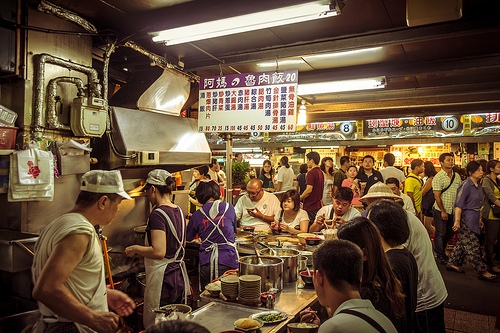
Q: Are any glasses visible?
A: No, there are no glasses.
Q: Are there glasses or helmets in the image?
A: No, there are no glasses or helmets.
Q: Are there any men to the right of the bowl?
A: Yes, there is a man to the right of the bowl.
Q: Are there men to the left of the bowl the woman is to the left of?
A: No, the man is to the right of the bowl.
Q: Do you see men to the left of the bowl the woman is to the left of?
A: No, the man is to the right of the bowl.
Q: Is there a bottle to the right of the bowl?
A: No, there is a man to the right of the bowl.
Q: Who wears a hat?
A: The man wears a hat.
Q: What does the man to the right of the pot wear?
A: The man wears a hat.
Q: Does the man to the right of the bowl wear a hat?
A: Yes, the man wears a hat.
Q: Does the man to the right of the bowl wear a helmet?
A: No, the man wears a hat.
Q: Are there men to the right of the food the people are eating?
A: Yes, there is a man to the right of the food.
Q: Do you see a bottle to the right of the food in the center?
A: No, there is a man to the right of the food.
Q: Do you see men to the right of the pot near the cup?
A: Yes, there is a man to the right of the pot.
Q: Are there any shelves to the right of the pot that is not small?
A: No, there is a man to the right of the pot.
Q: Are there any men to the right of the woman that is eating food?
A: Yes, there is a man to the right of the woman.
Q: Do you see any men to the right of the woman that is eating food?
A: Yes, there is a man to the right of the woman.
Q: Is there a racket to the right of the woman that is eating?
A: No, there is a man to the right of the woman.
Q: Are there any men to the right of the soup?
A: Yes, there is a man to the right of the soup.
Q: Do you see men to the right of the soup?
A: Yes, there is a man to the right of the soup.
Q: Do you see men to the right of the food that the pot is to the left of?
A: Yes, there is a man to the right of the soup.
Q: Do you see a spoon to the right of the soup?
A: No, there is a man to the right of the soup.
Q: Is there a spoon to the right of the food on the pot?
A: No, there is a man to the right of the soup.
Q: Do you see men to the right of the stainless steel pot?
A: Yes, there is a man to the right of the pot.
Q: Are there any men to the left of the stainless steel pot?
A: No, the man is to the right of the pot.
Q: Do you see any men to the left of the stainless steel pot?
A: No, the man is to the right of the pot.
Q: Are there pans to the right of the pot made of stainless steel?
A: No, there is a man to the right of the pot.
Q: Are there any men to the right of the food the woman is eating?
A: Yes, there is a man to the right of the food.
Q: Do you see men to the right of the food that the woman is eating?
A: Yes, there is a man to the right of the food.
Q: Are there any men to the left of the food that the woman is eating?
A: No, the man is to the right of the food.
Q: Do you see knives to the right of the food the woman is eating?
A: No, there is a man to the right of the food.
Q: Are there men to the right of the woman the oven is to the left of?
A: Yes, there is a man to the right of the woman.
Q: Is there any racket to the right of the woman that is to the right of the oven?
A: No, there is a man to the right of the woman.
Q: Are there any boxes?
A: No, there are no boxes.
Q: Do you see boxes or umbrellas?
A: No, there are no boxes or umbrellas.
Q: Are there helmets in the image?
A: No, there are no helmets.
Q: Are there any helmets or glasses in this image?
A: No, there are no helmets or glasses.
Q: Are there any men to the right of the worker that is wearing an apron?
A: Yes, there is a man to the right of the worker.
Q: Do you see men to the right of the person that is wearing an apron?
A: Yes, there is a man to the right of the worker.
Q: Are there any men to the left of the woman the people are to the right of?
A: Yes, there is a man to the left of the woman.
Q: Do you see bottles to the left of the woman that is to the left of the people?
A: No, there is a man to the left of the woman.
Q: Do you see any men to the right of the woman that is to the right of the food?
A: Yes, there is a man to the right of the woman.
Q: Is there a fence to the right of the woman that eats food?
A: No, there is a man to the right of the woman.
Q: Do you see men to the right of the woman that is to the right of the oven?
A: Yes, there is a man to the right of the woman.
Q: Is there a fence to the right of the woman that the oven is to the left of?
A: No, there is a man to the right of the woman.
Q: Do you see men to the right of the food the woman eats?
A: Yes, there is a man to the right of the food.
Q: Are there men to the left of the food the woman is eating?
A: No, the man is to the right of the food.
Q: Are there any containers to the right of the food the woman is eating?
A: No, there is a man to the right of the food.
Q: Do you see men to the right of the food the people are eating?
A: Yes, there is a man to the right of the food.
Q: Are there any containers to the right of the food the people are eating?
A: No, there is a man to the right of the food.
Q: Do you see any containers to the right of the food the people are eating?
A: No, there is a man to the right of the food.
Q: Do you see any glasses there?
A: No, there are no glasses.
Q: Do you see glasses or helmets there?
A: No, there are no glasses or helmets.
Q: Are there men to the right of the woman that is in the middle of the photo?
A: Yes, there is a man to the right of the woman.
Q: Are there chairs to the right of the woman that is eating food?
A: No, there is a man to the right of the woman.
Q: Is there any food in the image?
A: Yes, there is food.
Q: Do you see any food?
A: Yes, there is food.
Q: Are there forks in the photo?
A: No, there are no forks.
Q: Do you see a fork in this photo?
A: No, there are no forks.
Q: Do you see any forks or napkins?
A: No, there are no forks or napkins.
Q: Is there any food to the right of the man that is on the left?
A: Yes, there is food to the right of the man.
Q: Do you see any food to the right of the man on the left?
A: Yes, there is food to the right of the man.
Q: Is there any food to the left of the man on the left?
A: No, the food is to the right of the man.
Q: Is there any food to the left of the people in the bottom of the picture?
A: Yes, there is food to the left of the people.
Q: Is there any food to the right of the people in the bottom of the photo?
A: No, the food is to the left of the people.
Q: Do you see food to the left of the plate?
A: Yes, there is food to the left of the plate.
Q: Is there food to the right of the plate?
A: No, the food is to the left of the plate.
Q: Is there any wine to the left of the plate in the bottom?
A: No, there is food to the left of the plate.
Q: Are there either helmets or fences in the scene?
A: No, there are no fences or helmets.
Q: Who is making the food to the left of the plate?
A: The man is making the food.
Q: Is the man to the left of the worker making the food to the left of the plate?
A: Yes, the man is making the food.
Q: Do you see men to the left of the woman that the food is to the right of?
A: Yes, there is a man to the left of the woman.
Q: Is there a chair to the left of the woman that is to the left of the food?
A: No, there is a man to the left of the woman.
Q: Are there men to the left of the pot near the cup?
A: Yes, there is a man to the left of the pot.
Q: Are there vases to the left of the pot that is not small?
A: No, there is a man to the left of the pot.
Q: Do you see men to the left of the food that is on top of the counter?
A: Yes, there is a man to the left of the food.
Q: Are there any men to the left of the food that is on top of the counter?
A: Yes, there is a man to the left of the food.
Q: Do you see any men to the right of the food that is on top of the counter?
A: No, the man is to the left of the food.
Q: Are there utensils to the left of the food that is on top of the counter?
A: No, there is a man to the left of the food.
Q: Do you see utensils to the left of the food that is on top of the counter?
A: No, there is a man to the left of the food.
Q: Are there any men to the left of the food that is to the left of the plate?
A: Yes, there is a man to the left of the food.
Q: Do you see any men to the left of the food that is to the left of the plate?
A: Yes, there is a man to the left of the food.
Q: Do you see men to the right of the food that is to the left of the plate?
A: No, the man is to the left of the food.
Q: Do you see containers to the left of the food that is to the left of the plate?
A: No, there is a man to the left of the food.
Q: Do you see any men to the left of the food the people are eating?
A: Yes, there is a man to the left of the food.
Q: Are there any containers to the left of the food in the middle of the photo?
A: No, there is a man to the left of the food.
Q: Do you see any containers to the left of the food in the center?
A: No, there is a man to the left of the food.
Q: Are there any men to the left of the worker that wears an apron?
A: Yes, there is a man to the left of the worker.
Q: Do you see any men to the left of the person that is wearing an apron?
A: Yes, there is a man to the left of the worker.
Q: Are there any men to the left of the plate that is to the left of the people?
A: Yes, there is a man to the left of the plate.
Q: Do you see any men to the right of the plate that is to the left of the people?
A: No, the man is to the left of the plate.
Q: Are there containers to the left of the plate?
A: No, there is a man to the left of the plate.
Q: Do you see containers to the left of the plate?
A: No, there is a man to the left of the plate.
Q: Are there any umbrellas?
A: No, there are no umbrellas.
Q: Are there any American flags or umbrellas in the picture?
A: No, there are no umbrellas or American flags.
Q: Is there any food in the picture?
A: Yes, there is food.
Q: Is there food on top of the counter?
A: Yes, there is food on top of the counter.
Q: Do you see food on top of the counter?
A: Yes, there is food on top of the counter.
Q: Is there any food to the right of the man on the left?
A: Yes, there is food to the right of the man.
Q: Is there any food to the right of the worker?
A: Yes, there is food to the right of the worker.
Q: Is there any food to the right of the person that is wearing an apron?
A: Yes, there is food to the right of the worker.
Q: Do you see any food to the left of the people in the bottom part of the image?
A: Yes, there is food to the left of the people.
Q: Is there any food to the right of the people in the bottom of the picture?
A: No, the food is to the left of the people.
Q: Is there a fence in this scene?
A: No, there are no fences.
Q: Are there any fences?
A: No, there are no fences.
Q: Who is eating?
A: The man is eating.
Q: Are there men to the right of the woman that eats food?
A: Yes, there is a man to the right of the woman.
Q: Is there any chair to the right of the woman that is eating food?
A: No, there is a man to the right of the woman.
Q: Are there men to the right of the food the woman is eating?
A: Yes, there is a man to the right of the food.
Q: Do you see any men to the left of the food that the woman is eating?
A: No, the man is to the right of the food.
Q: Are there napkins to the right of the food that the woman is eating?
A: No, there is a man to the right of the food.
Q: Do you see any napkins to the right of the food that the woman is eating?
A: No, there is a man to the right of the food.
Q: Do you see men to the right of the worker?
A: Yes, there is a man to the right of the worker.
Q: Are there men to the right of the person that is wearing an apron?
A: Yes, there is a man to the right of the worker.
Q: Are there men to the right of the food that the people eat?
A: Yes, there is a man to the right of the food.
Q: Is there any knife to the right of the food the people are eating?
A: No, there is a man to the right of the food.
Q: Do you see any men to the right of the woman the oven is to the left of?
A: Yes, there is a man to the right of the woman.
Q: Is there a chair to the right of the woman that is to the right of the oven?
A: No, there is a man to the right of the woman.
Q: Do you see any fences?
A: No, there are no fences.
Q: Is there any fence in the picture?
A: No, there are no fences.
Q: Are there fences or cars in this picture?
A: No, there are no fences or cars.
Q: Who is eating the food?
A: The people are eating the food.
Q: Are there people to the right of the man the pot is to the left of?
A: Yes, there are people to the right of the man.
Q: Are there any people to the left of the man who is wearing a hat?
A: No, the people are to the right of the man.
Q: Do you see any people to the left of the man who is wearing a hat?
A: No, the people are to the right of the man.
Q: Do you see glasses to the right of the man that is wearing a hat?
A: No, there are people to the right of the man.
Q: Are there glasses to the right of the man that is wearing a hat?
A: No, there are people to the right of the man.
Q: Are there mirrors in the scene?
A: No, there are no mirrors.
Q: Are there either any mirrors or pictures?
A: No, there are no mirrors or pictures.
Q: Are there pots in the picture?
A: Yes, there is a pot.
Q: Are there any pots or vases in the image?
A: Yes, there is a pot.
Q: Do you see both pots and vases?
A: No, there is a pot but no vases.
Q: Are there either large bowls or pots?
A: Yes, there is a large pot.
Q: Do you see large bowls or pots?
A: Yes, there is a large pot.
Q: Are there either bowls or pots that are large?
A: Yes, the pot is large.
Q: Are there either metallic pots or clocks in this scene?
A: Yes, there is a metal pot.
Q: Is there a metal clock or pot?
A: Yes, there is a metal pot.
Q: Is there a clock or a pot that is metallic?
A: Yes, the pot is metallic.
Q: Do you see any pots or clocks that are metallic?
A: Yes, the pot is metallic.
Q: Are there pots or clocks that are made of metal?
A: Yes, the pot is made of metal.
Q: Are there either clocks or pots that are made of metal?
A: Yes, the pot is made of metal.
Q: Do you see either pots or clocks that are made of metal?
A: Yes, the pot is made of metal.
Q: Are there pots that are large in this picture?
A: Yes, there is a large pot.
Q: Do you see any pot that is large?
A: Yes, there is a pot that is large.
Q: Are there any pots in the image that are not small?
A: Yes, there is a large pot.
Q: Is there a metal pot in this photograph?
A: Yes, there is a metal pot.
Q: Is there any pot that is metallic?
A: Yes, there is a pot that is metallic.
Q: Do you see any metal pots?
A: Yes, there is a pot that is made of metal.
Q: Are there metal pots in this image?
A: Yes, there is a pot that is made of metal.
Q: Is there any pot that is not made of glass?
A: Yes, there is a pot that is made of metal.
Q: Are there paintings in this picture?
A: No, there are no paintings.